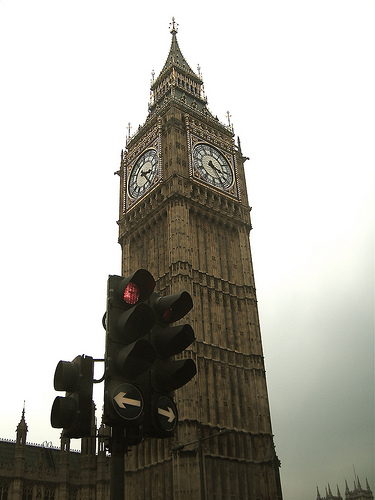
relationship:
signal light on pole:
[119, 268, 199, 394] [108, 432, 128, 498]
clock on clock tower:
[191, 141, 235, 190] [107, 13, 282, 498]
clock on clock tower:
[125, 147, 160, 194] [107, 13, 282, 498]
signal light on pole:
[119, 268, 199, 394] [111, 453, 127, 498]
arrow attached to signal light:
[111, 388, 143, 411] [107, 261, 157, 385]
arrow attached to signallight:
[158, 405, 176, 423] [50, 268, 197, 498]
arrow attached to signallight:
[111, 388, 143, 411] [50, 268, 197, 498]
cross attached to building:
[118, 118, 138, 137] [110, 15, 286, 499]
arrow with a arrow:
[111, 388, 143, 411] [114, 390, 141, 409]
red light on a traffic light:
[117, 277, 143, 305] [91, 265, 153, 427]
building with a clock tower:
[6, 14, 302, 499] [107, 13, 282, 498]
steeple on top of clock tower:
[146, 18, 205, 98] [107, 13, 282, 498]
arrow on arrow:
[111, 388, 143, 411] [111, 388, 143, 411]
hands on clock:
[208, 161, 220, 173] [188, 136, 235, 193]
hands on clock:
[208, 157, 225, 186] [188, 136, 235, 193]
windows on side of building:
[22, 480, 62, 499] [9, 456, 96, 498]